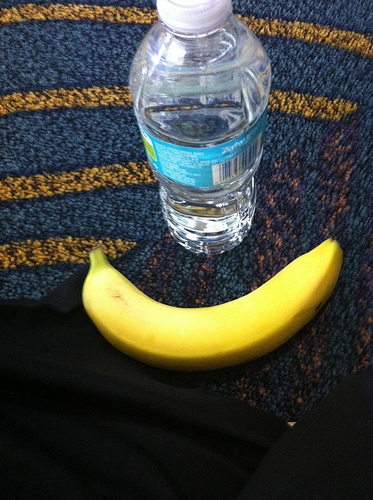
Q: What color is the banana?
A: Yellow.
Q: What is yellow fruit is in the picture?
A: A banana.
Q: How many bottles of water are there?
A: One.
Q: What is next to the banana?
A: A water bottle.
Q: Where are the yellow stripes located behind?
A: The water bottle.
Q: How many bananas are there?
A: One.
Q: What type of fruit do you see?
A: A banana.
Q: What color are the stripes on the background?
A: Yellow.